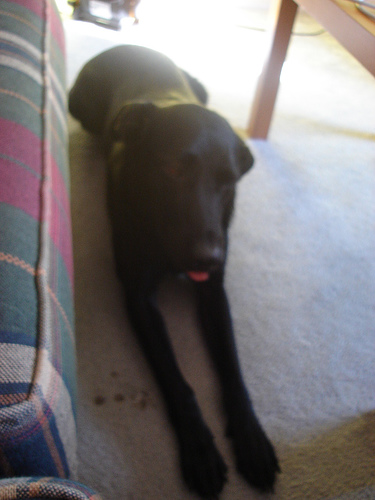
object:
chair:
[246, 0, 372, 190]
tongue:
[188, 270, 209, 281]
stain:
[91, 371, 150, 410]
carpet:
[208, 46, 372, 167]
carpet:
[74, 0, 122, 64]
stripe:
[2, 343, 77, 478]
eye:
[215, 170, 230, 185]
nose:
[187, 237, 224, 263]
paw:
[231, 422, 280, 492]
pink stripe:
[0, 116, 75, 288]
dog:
[64, 45, 281, 494]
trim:
[271, 406, 360, 494]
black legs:
[127, 301, 218, 451]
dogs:
[64, 41, 295, 485]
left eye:
[161, 162, 188, 182]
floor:
[77, 0, 375, 500]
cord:
[212, 7, 302, 136]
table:
[242, 1, 373, 144]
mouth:
[185, 254, 221, 284]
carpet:
[282, 309, 350, 412]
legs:
[195, 288, 280, 490]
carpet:
[87, 361, 159, 500]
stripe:
[9, 132, 57, 210]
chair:
[3, 0, 80, 500]